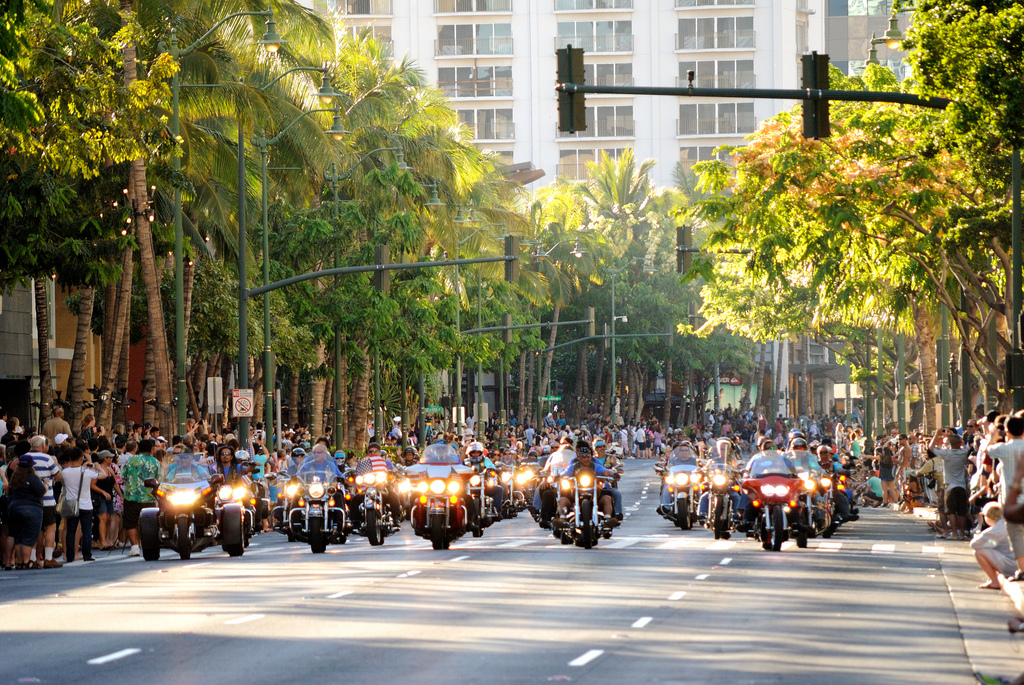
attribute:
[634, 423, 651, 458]
person — standing up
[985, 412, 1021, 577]
person — standing up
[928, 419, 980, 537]
person — standing up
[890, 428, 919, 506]
person — standing up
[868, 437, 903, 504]
person — standing up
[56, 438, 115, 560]
person — standing up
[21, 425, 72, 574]
person — standing up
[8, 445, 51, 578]
person — standing 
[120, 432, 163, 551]
person — standing 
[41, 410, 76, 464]
person — standing 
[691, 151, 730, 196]
leaves — green 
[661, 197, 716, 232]
leaves — green 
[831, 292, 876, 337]
leaves — green 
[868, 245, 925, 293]
leaves — green 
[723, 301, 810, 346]
leaves — green 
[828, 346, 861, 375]
leaves — green 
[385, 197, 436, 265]
leaves — green 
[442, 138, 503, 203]
leaves — green 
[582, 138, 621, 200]
leaves — green 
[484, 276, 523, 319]
leaves — green 